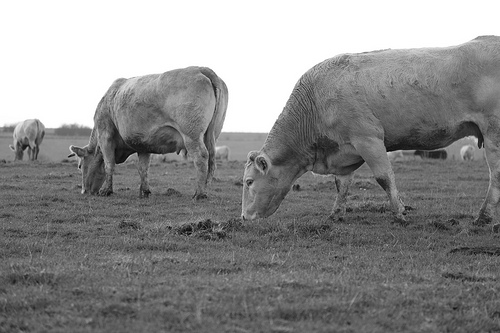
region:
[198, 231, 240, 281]
part of a ground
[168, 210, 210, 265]
part of a field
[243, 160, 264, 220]
part of an eye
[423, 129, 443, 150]
part of a stomach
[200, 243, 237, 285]
part of a field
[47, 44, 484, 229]
The cows are grazing on the grass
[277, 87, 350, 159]
The cow has wrinkles on his neck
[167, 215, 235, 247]
There is cow poop on the field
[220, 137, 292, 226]
The cow is eating grass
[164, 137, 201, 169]
The cow has udders underneath it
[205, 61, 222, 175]
The cow has a long tail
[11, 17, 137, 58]
The sky is cloudy with no sun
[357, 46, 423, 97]
The cow has short hair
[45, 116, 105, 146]
There are trees in the background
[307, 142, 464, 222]
The cow has two front legs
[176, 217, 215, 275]
part of some sand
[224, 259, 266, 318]
part of a grass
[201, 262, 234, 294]
part of a frass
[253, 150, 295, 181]
left ear of cow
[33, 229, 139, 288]
sprigs of grass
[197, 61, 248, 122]
tail of cow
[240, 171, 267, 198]
left eye of front cow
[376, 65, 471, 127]
side of cow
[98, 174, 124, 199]
hoove of cow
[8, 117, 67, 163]
cow facing away from camera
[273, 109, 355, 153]
wrinkles on cow's neck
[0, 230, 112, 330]
grass on lower left side of photo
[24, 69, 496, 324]
black and white picture of cows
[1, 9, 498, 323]
cows are grazing in a pasture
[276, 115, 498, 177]
the cow is wet underneath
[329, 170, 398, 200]
the cow's knees are wet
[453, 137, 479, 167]
a white cow is in the background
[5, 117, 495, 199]
a hill is in the background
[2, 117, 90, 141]
bushes are in the background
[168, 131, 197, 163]
the udder of the cow is wet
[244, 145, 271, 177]
the ears of the cow has a white trim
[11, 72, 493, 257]
all the cows have their head down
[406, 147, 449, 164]
a black cow is in the field